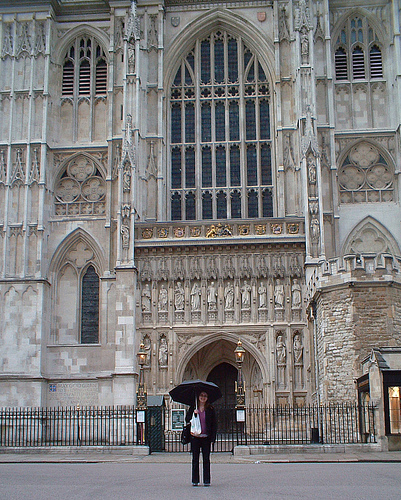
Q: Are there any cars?
A: No, there are no cars.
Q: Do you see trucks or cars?
A: No, there are no cars or trucks.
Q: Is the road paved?
A: Yes, the road is paved.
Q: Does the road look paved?
A: Yes, the road is paved.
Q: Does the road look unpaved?
A: No, the road is paved.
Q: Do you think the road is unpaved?
A: No, the road is paved.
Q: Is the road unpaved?
A: No, the road is paved.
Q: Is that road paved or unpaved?
A: The road is paved.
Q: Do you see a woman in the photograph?
A: Yes, there is a woman.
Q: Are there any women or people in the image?
A: Yes, there is a woman.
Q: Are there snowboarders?
A: No, there are no snowboarders.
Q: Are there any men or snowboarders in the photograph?
A: No, there are no snowboarders or men.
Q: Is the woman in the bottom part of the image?
A: Yes, the woman is in the bottom of the image.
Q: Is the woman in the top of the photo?
A: No, the woman is in the bottom of the image.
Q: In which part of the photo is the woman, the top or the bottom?
A: The woman is in the bottom of the image.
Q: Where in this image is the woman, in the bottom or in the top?
A: The woman is in the bottom of the image.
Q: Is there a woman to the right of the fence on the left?
A: Yes, there is a woman to the right of the fence.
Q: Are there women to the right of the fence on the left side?
A: Yes, there is a woman to the right of the fence.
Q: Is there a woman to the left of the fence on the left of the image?
A: No, the woman is to the right of the fence.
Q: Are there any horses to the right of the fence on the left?
A: No, there is a woman to the right of the fence.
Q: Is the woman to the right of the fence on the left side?
A: Yes, the woman is to the right of the fence.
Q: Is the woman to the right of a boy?
A: No, the woman is to the right of the fence.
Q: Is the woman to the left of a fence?
A: No, the woman is to the right of a fence.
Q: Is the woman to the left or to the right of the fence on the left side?
A: The woman is to the right of the fence.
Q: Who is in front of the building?
A: The woman is in front of the building.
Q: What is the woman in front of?
A: The woman is in front of the building.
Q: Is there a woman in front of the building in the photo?
A: Yes, there is a woman in front of the building.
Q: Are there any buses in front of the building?
A: No, there is a woman in front of the building.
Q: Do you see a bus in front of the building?
A: No, there is a woman in front of the building.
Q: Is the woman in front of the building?
A: Yes, the woman is in front of the building.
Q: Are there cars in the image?
A: No, there are no cars.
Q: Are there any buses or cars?
A: No, there are no cars or buses.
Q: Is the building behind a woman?
A: Yes, the building is behind a woman.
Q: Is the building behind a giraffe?
A: No, the building is behind a woman.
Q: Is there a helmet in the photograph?
A: No, there are no helmets.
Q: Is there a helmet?
A: No, there are no helmets.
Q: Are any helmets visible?
A: No, there are no helmets.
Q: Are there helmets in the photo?
A: No, there are no helmets.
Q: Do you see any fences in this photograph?
A: Yes, there is a fence.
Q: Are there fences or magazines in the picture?
A: Yes, there is a fence.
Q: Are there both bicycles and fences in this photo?
A: No, there is a fence but no bicycles.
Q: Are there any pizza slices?
A: No, there are no pizza slices.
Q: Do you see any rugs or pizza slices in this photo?
A: No, there are no pizza slices or rugs.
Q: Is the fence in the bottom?
A: Yes, the fence is in the bottom of the image.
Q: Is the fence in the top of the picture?
A: No, the fence is in the bottom of the image.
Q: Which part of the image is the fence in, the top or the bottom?
A: The fence is in the bottom of the image.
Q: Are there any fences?
A: Yes, there is a fence.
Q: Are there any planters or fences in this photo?
A: Yes, there is a fence.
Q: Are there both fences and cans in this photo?
A: No, there is a fence but no cans.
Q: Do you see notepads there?
A: No, there are no notepads.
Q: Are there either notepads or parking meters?
A: No, there are no notepads or parking meters.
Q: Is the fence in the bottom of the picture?
A: Yes, the fence is in the bottom of the image.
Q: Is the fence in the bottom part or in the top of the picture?
A: The fence is in the bottom of the image.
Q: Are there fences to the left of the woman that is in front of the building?
A: Yes, there is a fence to the left of the woman.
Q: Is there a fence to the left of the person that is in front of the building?
A: Yes, there is a fence to the left of the woman.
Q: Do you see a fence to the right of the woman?
A: No, the fence is to the left of the woman.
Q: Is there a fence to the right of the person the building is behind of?
A: No, the fence is to the left of the woman.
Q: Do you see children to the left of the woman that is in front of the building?
A: No, there is a fence to the left of the woman.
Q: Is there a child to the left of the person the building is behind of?
A: No, there is a fence to the left of the woman.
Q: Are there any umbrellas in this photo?
A: Yes, there is an umbrella.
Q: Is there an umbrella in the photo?
A: Yes, there is an umbrella.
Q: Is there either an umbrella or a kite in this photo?
A: Yes, there is an umbrella.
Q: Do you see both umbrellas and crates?
A: No, there is an umbrella but no crates.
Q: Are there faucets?
A: No, there are no faucets.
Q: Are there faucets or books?
A: No, there are no faucets or books.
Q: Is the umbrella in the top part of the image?
A: No, the umbrella is in the bottom of the image.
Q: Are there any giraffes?
A: No, there are no giraffes.